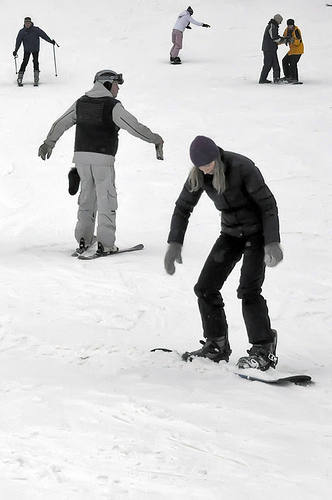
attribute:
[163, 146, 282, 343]
clothing — dark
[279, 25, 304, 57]
jacket — yellow, orange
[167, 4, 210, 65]
snowboarder — unbalanced